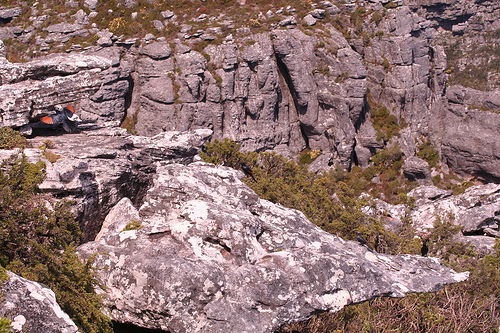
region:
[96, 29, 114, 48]
rocks on a mountain side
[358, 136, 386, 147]
rocks on a mountain side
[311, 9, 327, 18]
rocks on a mountain side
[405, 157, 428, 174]
rocks on a mountain side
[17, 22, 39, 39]
rocks on a mountain side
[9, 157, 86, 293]
trees on a mountain side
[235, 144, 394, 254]
trees on a mountain side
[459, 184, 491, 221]
rocks on a mountain side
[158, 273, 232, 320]
rocks on a mountain side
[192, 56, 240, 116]
rocks on a mountain side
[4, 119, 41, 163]
patch of green scrub on stone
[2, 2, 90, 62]
patch of green scrub on stone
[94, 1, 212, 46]
patch of green scrub on stone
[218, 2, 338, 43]
patch of green scrub on stone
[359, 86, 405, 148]
patch of green scrub on stone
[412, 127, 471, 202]
patch of green scrub on stone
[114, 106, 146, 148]
patch of green scrub on stone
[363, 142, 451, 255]
patch of green scrub on stone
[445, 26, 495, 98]
patch of green scrub on stone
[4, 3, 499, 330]
Attractive rock formation.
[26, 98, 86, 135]
Black and orange wild bird.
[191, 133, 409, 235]
Bushes in between rocks.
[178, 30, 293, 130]
Rocks looking like Buddha statues.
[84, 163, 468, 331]
One big piece of rock.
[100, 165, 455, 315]
White and brown rock.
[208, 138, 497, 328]
Plants appear to be very dry.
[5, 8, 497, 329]
The area is rather barren.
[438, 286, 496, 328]
Very dry plant roots.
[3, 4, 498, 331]
This area belongs to a desert.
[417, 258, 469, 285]
Pointed end of rock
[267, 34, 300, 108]
Deep dark shadow between rocks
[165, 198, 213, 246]
White spots on large rock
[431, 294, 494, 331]
Patch of wooden brush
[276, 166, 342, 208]
Yellow green weeds behind rock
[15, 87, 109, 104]
Lines running across large rock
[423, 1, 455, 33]
Dark shadows on cliff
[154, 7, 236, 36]
Pieces of rocks showing through moss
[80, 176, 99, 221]
Dark grey spot on rocks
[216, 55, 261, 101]
Cracks running down rocks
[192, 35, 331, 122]
this is a rock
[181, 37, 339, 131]
the rock is big in size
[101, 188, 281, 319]
the rock is white in color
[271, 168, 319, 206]
these are the grass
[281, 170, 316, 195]
the grass are green in color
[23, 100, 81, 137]
this is a bear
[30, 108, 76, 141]
the bear is black in color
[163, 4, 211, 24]
the grass are dry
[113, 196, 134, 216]
the rock is sharp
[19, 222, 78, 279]
the grass are bright